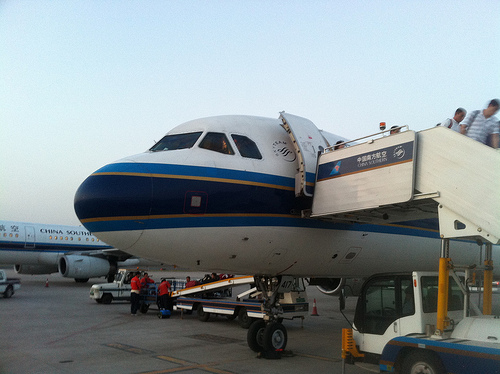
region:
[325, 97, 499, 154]
passengers exiting a plane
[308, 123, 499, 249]
a ramp of stairs attached to the plane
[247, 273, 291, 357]
front tires on the plane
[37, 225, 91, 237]
a logo on the side of the airplane in the background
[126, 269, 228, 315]
airport workers wearing red shirts on the runway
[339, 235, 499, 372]
a truck lifting the set of stairs to the airplane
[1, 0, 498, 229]
clear blue skies that are darkening as the day advances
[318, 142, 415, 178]
a logo on the side of the staircase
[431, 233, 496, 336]
yellow poles on the truck lifting the stairs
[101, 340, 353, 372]
yellow lines painted on the runway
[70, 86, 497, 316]
this is a plane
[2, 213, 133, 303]
this is a plane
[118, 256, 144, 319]
this is a person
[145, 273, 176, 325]
this is a person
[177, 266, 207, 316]
this is a person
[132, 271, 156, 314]
this is a person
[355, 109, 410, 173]
this is a person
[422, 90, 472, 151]
this is a person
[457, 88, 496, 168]
this is a person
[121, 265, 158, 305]
this is a person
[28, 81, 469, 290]
white and blue plane at boarding gate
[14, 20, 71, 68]
white clouds in blue sky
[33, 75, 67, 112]
white clouds in blue sky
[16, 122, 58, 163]
white clouds in blue sky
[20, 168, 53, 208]
white clouds in blue sky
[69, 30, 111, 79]
white clouds in blue sky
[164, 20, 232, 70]
white clouds in blue sky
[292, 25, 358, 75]
white clouds in blue sky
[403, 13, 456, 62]
white clouds in blue sky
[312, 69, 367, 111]
white clouds in blue sky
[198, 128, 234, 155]
the window of a plane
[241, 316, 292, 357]
the wheel of a plane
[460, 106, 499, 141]
a man's white striped shirt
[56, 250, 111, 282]
the engine of a plane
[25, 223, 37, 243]
the door of a plane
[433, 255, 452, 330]
a tall yellow pole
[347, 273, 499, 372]
part of a truck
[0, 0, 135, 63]
part of a blue sky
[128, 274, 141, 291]
a man's red shirt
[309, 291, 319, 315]
a tall orange and white cone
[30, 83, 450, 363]
blue and white airplane at boarding gate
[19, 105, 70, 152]
white clouds in blue sky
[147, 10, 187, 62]
white clouds in blue sky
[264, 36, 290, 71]
white clouds in blue sky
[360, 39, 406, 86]
white clouds in blue sky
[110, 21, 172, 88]
white clouds in blue sky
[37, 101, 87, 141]
white clouds in blue sky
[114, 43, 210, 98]
white clouds in blue sky